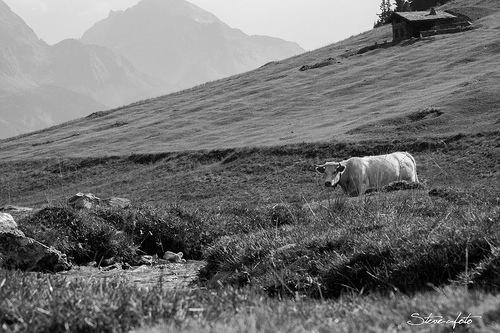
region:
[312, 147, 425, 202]
cow walking in grass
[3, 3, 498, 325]
black and white photo of cow walking across pasture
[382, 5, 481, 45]
house on grass of pasture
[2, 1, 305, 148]
mountains in horizon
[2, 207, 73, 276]
rocks on ground in pasture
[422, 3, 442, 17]
chimeny on house roof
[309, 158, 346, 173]
two cow ears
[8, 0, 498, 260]
field of grass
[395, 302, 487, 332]
nameof photographer in white script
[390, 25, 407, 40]
windows on side of house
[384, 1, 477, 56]
cabin on a hill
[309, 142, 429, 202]
white cow in a field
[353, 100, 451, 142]
crater in the ground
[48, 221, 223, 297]
water between two banks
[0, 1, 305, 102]
mountains in the distance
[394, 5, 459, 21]
roof with a chimney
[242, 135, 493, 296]
grassy slope with a cow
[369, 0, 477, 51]
cabin with distant trees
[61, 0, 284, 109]
mountain shrouded with fog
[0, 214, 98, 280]
rock beside a stream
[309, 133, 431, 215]
this is a cow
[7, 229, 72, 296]
a rock on the ground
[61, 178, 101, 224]
a rock on the ground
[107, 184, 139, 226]
a rock on the ground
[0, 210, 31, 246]
a rock on the ground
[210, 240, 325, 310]
this is grass on the ground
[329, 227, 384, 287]
this is grass on the ground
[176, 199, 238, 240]
this is grass on the ground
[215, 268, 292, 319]
this is grass on the ground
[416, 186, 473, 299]
this is grass on the ground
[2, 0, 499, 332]
The picture is black and white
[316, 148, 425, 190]
There is one cow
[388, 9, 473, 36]
There is one cottage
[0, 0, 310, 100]
There are mountains in the background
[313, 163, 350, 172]
The cow has two ears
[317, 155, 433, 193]
The cow is standing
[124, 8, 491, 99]
The house is on a hill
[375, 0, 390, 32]
Trees are beside the cottage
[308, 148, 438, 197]
The cow is standing in the grass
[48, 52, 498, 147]
The hill is grassy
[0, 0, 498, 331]
grayscale photo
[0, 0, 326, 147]
mountains in the distance, faded in photoshop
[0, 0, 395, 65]
sky, faded back in photoshop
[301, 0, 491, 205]
cow, a hundred yards or so beneath farm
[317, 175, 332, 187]
cow in photo has squared muzzle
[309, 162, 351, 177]
cow has darker ears, held perpendicular to head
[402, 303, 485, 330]
signature in corner, so photo likely requires licensing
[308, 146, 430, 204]
cow is blonde, or a light tan [in the cow world]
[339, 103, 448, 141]
a small pit in the pasture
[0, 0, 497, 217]
pastureland on the side of a hill, with two trees leading to more beyond